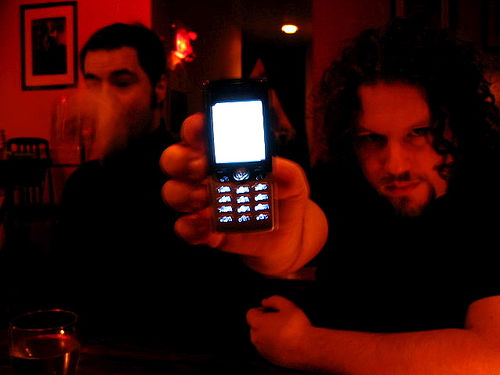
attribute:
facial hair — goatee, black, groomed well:
[373, 170, 436, 216]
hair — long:
[314, 57, 494, 220]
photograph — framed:
[30, 15, 66, 75]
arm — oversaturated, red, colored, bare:
[240, 296, 498, 373]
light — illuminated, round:
[276, 22, 299, 38]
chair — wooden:
[0, 135, 58, 202]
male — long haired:
[161, 15, 491, 373]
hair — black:
[299, 18, 484, 145]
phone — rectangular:
[201, 79, 284, 225]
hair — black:
[307, 22, 491, 192]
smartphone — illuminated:
[201, 80, 275, 231]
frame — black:
[15, 2, 78, 88]